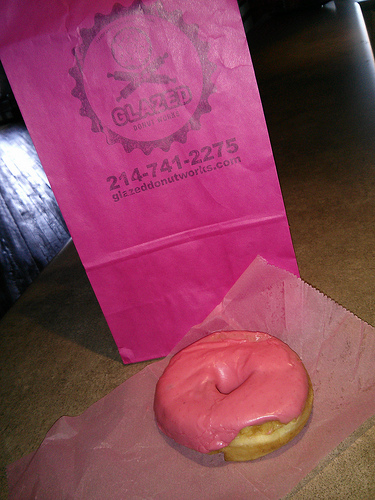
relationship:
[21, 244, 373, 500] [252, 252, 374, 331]
paper has edge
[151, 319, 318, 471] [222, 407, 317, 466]
donut has edge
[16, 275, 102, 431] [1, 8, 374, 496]
surface of table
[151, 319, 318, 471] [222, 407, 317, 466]
donut seen a side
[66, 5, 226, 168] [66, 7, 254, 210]
logo of a shop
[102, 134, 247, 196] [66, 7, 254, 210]
phone number for a donut shop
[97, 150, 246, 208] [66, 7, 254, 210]
website of shop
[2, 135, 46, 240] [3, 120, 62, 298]
light on blinds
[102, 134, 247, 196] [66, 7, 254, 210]
phone number of shop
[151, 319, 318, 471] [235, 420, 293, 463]
donut has unglazed part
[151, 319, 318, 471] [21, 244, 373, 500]
donut on top of wax paper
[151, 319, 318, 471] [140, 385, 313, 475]
donut has outline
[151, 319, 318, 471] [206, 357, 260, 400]
donut has a hole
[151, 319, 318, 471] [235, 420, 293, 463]
donut without icing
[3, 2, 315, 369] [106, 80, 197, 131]
bag says glazed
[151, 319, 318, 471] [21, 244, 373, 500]
doughnut on waxed paper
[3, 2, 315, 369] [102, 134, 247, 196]
bag says 214-741-2275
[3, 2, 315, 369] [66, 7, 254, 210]
bag has print black